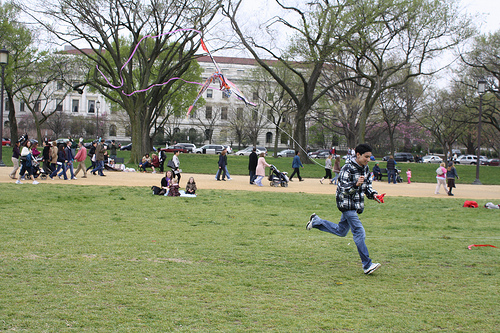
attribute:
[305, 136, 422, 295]
boy — running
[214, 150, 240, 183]
man — walking, young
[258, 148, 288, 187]
woman — pushing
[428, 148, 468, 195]
females — walking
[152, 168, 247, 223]
family — sitting, having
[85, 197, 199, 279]
grass — green, cut, large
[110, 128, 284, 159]
cars — lined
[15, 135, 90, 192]
people — crowded, together, walking, grouped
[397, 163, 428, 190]
child — small, sitting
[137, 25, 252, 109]
kite — blue, pulled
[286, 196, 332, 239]
shoe — black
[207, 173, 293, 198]
path — dirt, brown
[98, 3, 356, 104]
trees — bare, budding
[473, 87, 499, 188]
post — black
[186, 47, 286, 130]
building — large, white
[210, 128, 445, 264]
kid — running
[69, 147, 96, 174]
person — wearing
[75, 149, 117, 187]
jacket — red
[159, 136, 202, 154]
car — red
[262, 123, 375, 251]
man — pulling